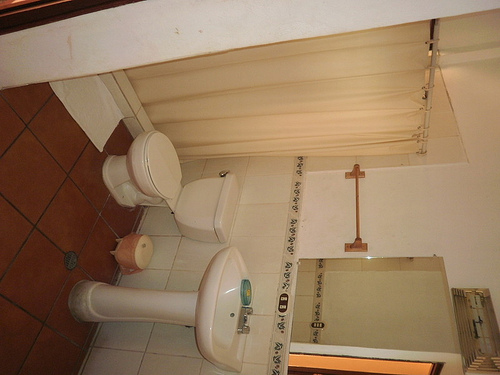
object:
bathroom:
[0, 0, 499, 374]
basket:
[110, 231, 153, 275]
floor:
[1, 42, 152, 374]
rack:
[344, 164, 368, 253]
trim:
[266, 155, 307, 374]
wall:
[75, 56, 499, 375]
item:
[241, 278, 252, 305]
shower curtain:
[123, 20, 440, 161]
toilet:
[102, 131, 238, 244]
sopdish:
[240, 278, 253, 306]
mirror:
[289, 256, 463, 356]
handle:
[219, 169, 230, 177]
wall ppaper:
[266, 156, 306, 375]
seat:
[144, 132, 182, 200]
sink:
[66, 245, 253, 375]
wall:
[76, 156, 308, 374]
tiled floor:
[0, 80, 147, 374]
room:
[2, 0, 500, 375]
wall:
[2, 2, 496, 96]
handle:
[237, 324, 250, 334]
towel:
[50, 72, 128, 153]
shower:
[122, 18, 442, 164]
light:
[426, 40, 468, 85]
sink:
[195, 246, 253, 374]